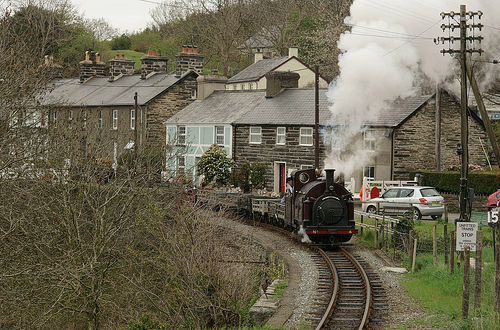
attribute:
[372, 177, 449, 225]
car — parked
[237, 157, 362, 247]
train — small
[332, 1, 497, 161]
steam — white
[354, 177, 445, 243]
car — silver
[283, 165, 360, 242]
frontcar — black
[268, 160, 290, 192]
door — red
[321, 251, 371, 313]
train tracks — Wooden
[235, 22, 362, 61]
building — middle, light blue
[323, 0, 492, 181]
steam — coming, rising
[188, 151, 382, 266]
train — black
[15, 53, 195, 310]
trees — bare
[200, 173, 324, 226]
cars — open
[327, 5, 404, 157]
smoke — Thick, white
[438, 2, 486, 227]
telephone pole — electric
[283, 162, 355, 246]
train — small, black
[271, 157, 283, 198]
door — red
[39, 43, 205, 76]
chimneys — brick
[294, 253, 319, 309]
rocks — Small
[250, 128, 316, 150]
windows — Many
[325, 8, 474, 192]
cloud — steam